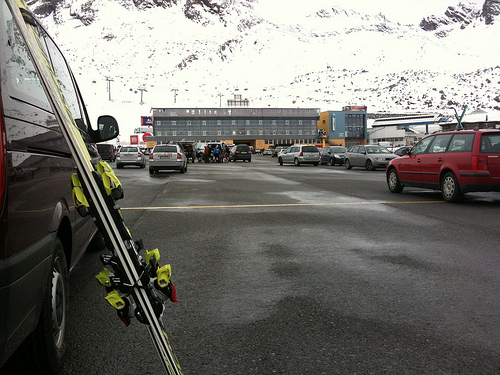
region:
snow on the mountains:
[68, 12, 477, 87]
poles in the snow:
[103, 75, 188, 102]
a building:
[149, 94, 401, 143]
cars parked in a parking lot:
[141, 135, 473, 204]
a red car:
[387, 131, 483, 183]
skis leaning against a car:
[5, 20, 222, 367]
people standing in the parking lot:
[172, 133, 265, 174]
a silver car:
[267, 138, 327, 174]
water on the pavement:
[198, 174, 410, 226]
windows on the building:
[345, 114, 361, 135]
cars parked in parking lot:
[129, 84, 376, 180]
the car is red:
[390, 124, 483, 203]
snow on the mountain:
[272, 31, 426, 79]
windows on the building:
[153, 102, 303, 136]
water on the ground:
[254, 230, 357, 312]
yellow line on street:
[210, 195, 310, 207]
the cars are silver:
[281, 140, 373, 170]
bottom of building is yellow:
[258, 134, 270, 151]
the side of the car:
[22, 145, 73, 235]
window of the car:
[0, 63, 47, 126]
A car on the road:
[380, 130, 499, 205]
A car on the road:
[342, 140, 385, 174]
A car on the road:
[323, 139, 348, 170]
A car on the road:
[278, 144, 317, 169]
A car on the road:
[230, 138, 258, 170]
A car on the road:
[144, 136, 195, 176]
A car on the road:
[118, 142, 145, 172]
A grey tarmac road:
[331, 259, 443, 361]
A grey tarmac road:
[178, 214, 303, 354]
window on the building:
[177, 114, 192, 124]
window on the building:
[256, 119, 260, 126]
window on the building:
[270, 119, 278, 129]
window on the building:
[284, 120, 290, 125]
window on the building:
[295, 117, 305, 127]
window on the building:
[297, 118, 303, 127]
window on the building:
[201, 129, 208, 136]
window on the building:
[257, 129, 267, 136]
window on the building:
[283, 128, 290, 135]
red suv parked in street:
[386, 128, 496, 198]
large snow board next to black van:
[12, 11, 182, 373]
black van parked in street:
[0, 4, 121, 367]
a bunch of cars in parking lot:
[4, 5, 494, 372]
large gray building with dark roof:
[154, 106, 322, 158]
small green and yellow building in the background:
[321, 108, 368, 148]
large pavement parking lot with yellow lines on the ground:
[68, 151, 498, 372]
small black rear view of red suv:
[395, 145, 414, 157]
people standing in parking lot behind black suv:
[204, 143, 231, 164]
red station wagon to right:
[381, 116, 498, 196]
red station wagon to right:
[375, 123, 498, 203]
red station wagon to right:
[375, 119, 498, 202]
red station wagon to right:
[378, 114, 498, 203]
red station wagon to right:
[380, 120, 497, 203]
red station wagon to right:
[384, 122, 499, 200]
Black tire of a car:
[440, 171, 464, 204]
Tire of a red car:
[439, 168, 461, 202]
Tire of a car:
[385, 167, 405, 196]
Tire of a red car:
[386, 164, 406, 194]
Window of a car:
[451, 133, 473, 151]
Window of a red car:
[448, 133, 472, 153]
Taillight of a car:
[175, 151, 181, 163]